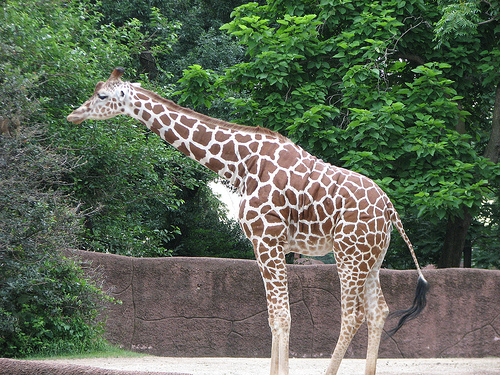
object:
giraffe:
[66, 66, 429, 375]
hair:
[382, 276, 432, 342]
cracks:
[135, 316, 233, 323]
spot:
[256, 158, 277, 183]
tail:
[382, 208, 430, 343]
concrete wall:
[63, 249, 500, 358]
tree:
[175, 0, 500, 270]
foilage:
[31, 62, 39, 71]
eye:
[97, 95, 110, 100]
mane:
[130, 83, 284, 143]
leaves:
[36, 11, 54, 26]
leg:
[327, 220, 382, 375]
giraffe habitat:
[0, 0, 500, 375]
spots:
[271, 189, 286, 207]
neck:
[127, 82, 279, 196]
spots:
[192, 124, 213, 147]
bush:
[0, 67, 103, 360]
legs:
[320, 230, 392, 375]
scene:
[0, 0, 500, 375]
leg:
[252, 242, 278, 375]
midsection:
[239, 165, 333, 257]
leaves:
[304, 107, 320, 122]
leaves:
[276, 19, 289, 26]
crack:
[303, 285, 332, 294]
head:
[66, 66, 130, 125]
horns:
[109, 67, 126, 80]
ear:
[118, 90, 126, 101]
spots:
[272, 169, 290, 191]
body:
[65, 66, 430, 375]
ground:
[0, 357, 500, 375]